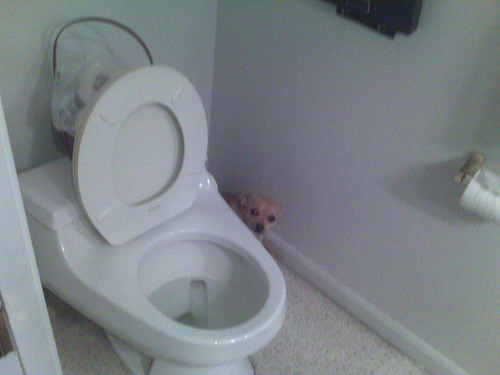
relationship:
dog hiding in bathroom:
[230, 185, 292, 240] [11, 5, 486, 366]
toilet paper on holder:
[462, 159, 497, 226] [447, 147, 482, 199]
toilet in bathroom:
[110, 213, 291, 373] [13, 7, 379, 312]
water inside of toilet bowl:
[146, 277, 238, 327] [18, 64, 290, 373]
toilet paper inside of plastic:
[43, 41, 144, 88] [39, 34, 75, 80]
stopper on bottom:
[97, 107, 119, 133] [83, 73, 201, 229]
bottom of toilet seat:
[83, 73, 201, 229] [61, 130, 146, 236]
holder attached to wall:
[447, 147, 482, 199] [219, 7, 497, 352]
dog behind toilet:
[230, 185, 292, 240] [110, 213, 291, 373]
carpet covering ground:
[42, 238, 428, 373] [29, 214, 442, 371]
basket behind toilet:
[53, 17, 154, 159] [110, 213, 291, 373]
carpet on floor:
[42, 238, 428, 373] [37, 215, 446, 372]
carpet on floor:
[42, 238, 428, 373] [36, 232, 442, 372]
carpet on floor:
[42, 238, 428, 373] [40, 247, 435, 373]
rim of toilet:
[125, 225, 278, 341] [110, 213, 291, 373]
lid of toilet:
[69, 66, 209, 250] [110, 213, 291, 373]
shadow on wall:
[441, 12, 499, 159] [219, 7, 497, 352]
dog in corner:
[230, 185, 292, 240] [193, 6, 239, 184]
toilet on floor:
[110, 213, 291, 373] [283, 323, 380, 372]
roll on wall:
[454, 162, 499, 226] [208, 0, 498, 372]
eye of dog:
[248, 207, 258, 214] [221, 187, 281, 240]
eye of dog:
[266, 213, 276, 225] [221, 187, 281, 240]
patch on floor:
[315, 331, 336, 356] [21, 197, 431, 373]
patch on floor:
[282, 340, 302, 363] [49, 257, 433, 374]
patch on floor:
[315, 331, 336, 356] [36, 232, 442, 372]